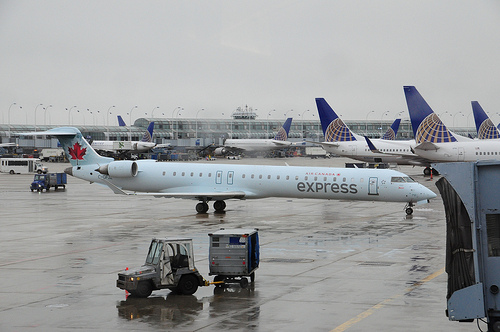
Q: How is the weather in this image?
A: It is rainy.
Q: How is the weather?
A: It is rainy.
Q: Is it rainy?
A: Yes, it is rainy.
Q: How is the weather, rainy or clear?
A: It is rainy.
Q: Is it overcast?
A: No, it is rainy.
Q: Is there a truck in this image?
A: Yes, there is a truck.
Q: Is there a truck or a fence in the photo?
A: Yes, there is a truck.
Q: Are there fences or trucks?
A: Yes, there is a truck.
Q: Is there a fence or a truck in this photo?
A: Yes, there is a truck.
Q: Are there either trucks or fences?
A: Yes, there is a truck.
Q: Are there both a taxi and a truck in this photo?
A: No, there is a truck but no taxis.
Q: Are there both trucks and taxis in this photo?
A: No, there is a truck but no taxis.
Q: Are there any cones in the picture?
A: No, there are no cones.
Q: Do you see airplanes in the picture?
A: Yes, there is an airplane.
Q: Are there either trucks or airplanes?
A: Yes, there is an airplane.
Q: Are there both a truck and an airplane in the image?
A: Yes, there are both an airplane and a truck.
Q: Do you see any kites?
A: No, there are no kites.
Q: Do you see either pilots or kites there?
A: No, there are no kites or pilots.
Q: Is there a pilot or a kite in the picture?
A: No, there are no kites or pilots.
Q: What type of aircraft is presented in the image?
A: The aircraft is an airplane.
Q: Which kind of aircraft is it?
A: The aircraft is an airplane.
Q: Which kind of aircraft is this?
A: This is an airplane.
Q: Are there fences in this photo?
A: No, there are no fences.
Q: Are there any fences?
A: No, there are no fences.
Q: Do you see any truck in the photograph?
A: Yes, there is a truck.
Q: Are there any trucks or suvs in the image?
A: Yes, there is a truck.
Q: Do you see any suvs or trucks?
A: Yes, there is a truck.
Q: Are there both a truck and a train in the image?
A: No, there is a truck but no trains.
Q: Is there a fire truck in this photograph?
A: No, there are no fire trucks.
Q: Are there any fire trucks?
A: No, there are no fire trucks.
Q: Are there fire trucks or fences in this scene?
A: No, there are no fire trucks or fences.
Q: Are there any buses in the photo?
A: Yes, there is a bus.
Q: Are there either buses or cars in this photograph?
A: Yes, there is a bus.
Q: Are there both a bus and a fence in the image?
A: No, there is a bus but no fences.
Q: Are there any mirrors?
A: No, there are no mirrors.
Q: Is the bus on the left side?
A: Yes, the bus is on the left of the image.